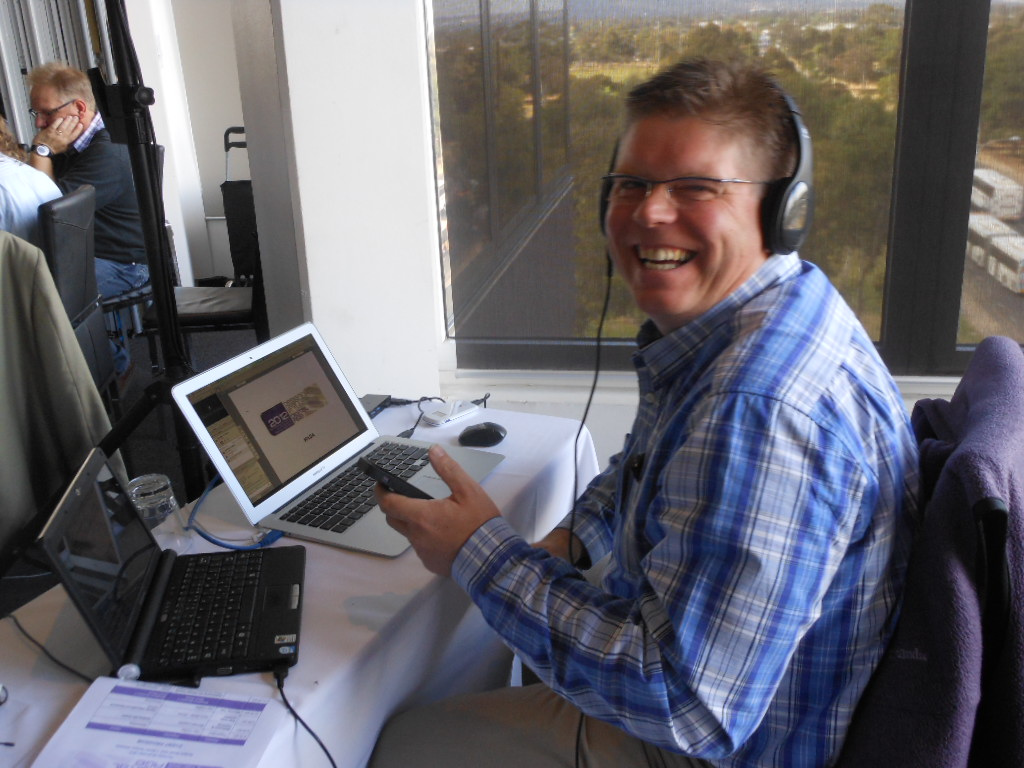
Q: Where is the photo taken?
A: In an office.